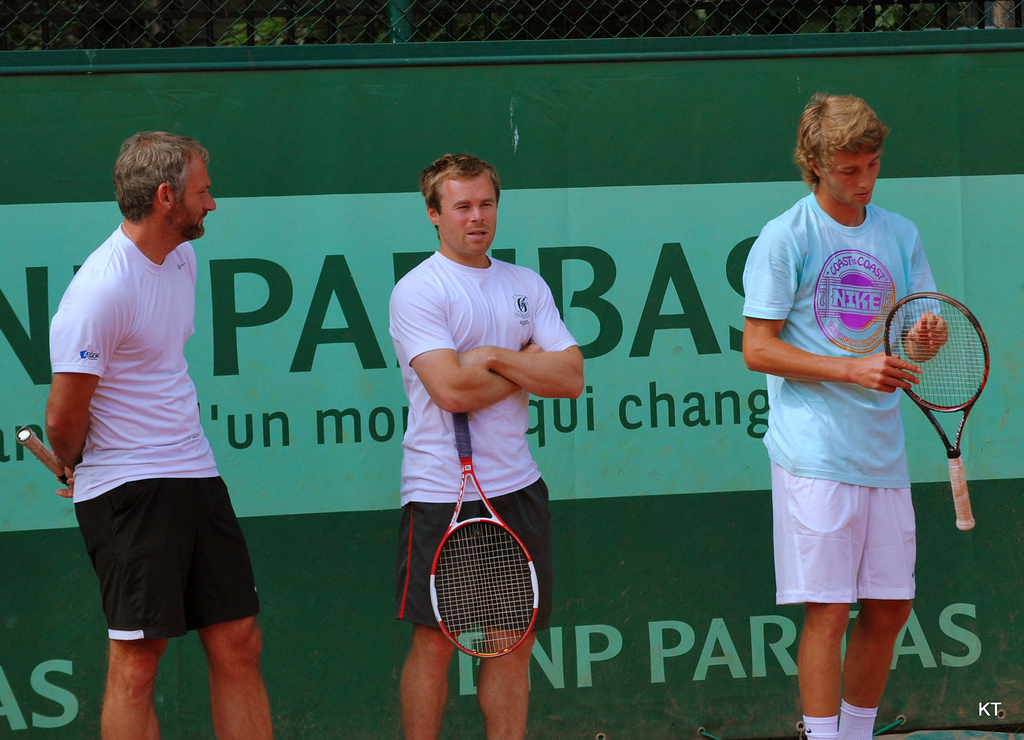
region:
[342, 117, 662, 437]
Man with arms folded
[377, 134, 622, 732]
man in grey shorts holding a tennis racket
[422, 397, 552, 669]
upside down tennis racket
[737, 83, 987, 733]
man in blue shirt holding tennis racket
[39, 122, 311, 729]
slouching man in black shorts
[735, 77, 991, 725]
man pick at tennis racket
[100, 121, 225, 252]
man with beard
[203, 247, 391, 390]
big letters saying PA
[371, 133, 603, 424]
man with muscled arms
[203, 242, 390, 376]
dark green letters on lighter green background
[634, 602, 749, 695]
light green letters on darker green background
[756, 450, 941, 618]
white, athletic shorts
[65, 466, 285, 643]
black athletic shorts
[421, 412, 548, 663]
red and white tennis racket with a black handle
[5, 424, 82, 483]
white tennis racket handle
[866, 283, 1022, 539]
black and red tennis racket with a white handle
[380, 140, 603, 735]
man standing with a tennis racket and arms crossed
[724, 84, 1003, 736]
man checking tennis racket strings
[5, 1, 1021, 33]
chain link fence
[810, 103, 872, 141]
blonder hair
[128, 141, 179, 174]
gray hair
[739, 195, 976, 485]
A light blue shirt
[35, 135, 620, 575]
Two men wearing white shirts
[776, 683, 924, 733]
A man has on white socks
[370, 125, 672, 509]
A guy has his arms crossed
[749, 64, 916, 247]
A man has light brown hair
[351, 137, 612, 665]
Guy is holding a tennis racket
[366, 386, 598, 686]
A racket is white and red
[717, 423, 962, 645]
A man has on white shorts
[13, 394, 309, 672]
Man wearing black shorts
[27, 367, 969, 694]
Three men are wearing shorts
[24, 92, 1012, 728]
three tennis players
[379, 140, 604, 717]
a young man holding a tennis racket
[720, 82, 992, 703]
a young man playing with a tennis racket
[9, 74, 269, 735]
a man with his hands behind his back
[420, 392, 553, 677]
a red tennis racket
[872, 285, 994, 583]
a black and white tennis racket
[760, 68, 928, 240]
a blonde haired man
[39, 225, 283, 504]
a white t shirt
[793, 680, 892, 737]
the tops of white socks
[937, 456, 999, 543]
a tennis racket handle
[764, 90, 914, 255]
A man is looking downwards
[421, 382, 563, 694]
A racket is red and white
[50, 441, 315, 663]
Guy wearing black shorts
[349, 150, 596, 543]
A man has on a white shirt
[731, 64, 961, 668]
A guy is wearing white shorts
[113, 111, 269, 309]
A guy has a beard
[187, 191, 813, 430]
Letters on a sign are green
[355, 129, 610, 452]
A man has his arms crossed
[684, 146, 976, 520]
Man wearing light blue shirt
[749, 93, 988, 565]
A man is looking at his racket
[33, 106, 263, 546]
A man is wearing a white shirt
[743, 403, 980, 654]
White shorts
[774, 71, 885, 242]
A guy has blonde hair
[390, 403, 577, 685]
A tennis racket is red and white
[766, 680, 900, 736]
White socks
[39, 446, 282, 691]
Dark green shorts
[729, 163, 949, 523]
A light blue t-shirt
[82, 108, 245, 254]
A man has a beard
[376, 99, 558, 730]
Man holding Red tennis racquet